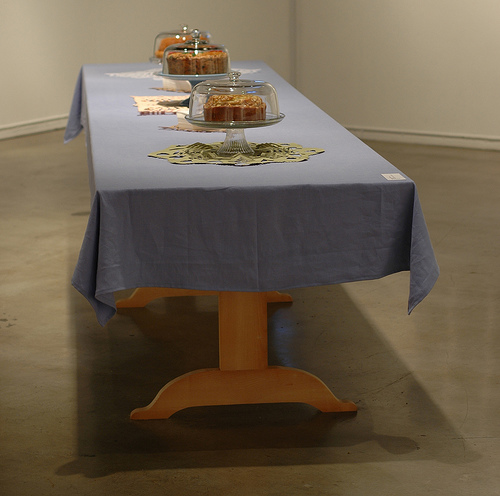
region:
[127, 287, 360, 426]
Wood leg on table.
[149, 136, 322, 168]
Green doily on table.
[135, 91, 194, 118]
Brown mat the table.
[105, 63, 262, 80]
White doily on the table.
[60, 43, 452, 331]
Blue table cloth on the table.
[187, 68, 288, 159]
Clear glass cake dish.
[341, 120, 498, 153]
White baseboard molding.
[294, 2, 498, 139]
White wall in the background.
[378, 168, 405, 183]
White card on the table.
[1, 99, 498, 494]
Gray floor under the table.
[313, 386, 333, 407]
part of a table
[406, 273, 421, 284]
part of a curtain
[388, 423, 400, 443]
part of a shadow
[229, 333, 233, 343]
part of a table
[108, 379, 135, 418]
part of the shadow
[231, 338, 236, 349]
part of a table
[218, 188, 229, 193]
edge of a table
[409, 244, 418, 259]
part of a curtain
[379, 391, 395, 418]
part of a shadow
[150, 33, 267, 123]
three brown colored cakes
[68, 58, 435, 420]
a brown colored wooden table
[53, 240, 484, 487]
shadow of the table on the floor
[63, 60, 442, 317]
a blue tablecloth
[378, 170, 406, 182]
a piece of white paper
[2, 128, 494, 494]
a gray colored concrete floor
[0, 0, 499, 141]
white colored walls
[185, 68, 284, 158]
a glass cake pedestal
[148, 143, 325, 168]
a tan colored doily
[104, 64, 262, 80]
a white doily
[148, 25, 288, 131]
Three cakes in a row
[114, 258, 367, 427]
Wooden legs of the table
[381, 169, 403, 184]
White label on the edge of the tablecloth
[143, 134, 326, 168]
Green mat underneath the cake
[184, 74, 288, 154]
Light brown cake in a glass carrier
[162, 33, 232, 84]
Light brown cake in a glass case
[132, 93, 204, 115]
White mat underneath a cake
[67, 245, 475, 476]
Black shadow of the table on the ground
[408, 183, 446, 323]
Corner of the blue tablecloth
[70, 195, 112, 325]
Blue corner of the tablecloth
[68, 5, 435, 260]
3 cakes on a table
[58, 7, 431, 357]
3 cakes in cake holders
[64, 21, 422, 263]
Three cakes in cake stands on table with blue tablecloth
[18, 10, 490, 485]
Three cakes on a table in a warehouse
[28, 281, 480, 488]
Shadow of a table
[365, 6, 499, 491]
White wall and cement flooring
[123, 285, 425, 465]
Table legs under table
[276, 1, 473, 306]
Edge of a table with blue tablecloth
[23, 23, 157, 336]
Blue tablecloth hanging on the corner of the table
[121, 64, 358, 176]
Glass cake holder on a green table mat